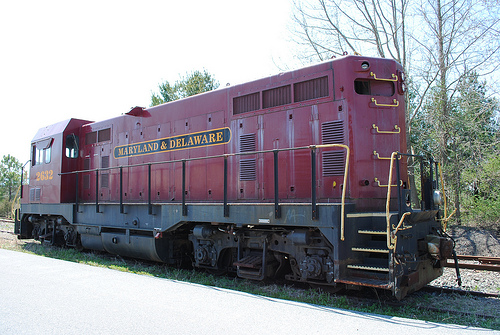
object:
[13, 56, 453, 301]
train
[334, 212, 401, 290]
staircase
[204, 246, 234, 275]
wheel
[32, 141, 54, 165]
window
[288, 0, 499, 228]
tree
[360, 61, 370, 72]
light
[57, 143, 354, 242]
rail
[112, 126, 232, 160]
logo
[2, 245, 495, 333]
track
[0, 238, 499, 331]
grass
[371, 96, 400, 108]
rung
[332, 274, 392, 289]
step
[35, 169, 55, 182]
logo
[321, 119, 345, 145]
vent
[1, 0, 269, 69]
sky